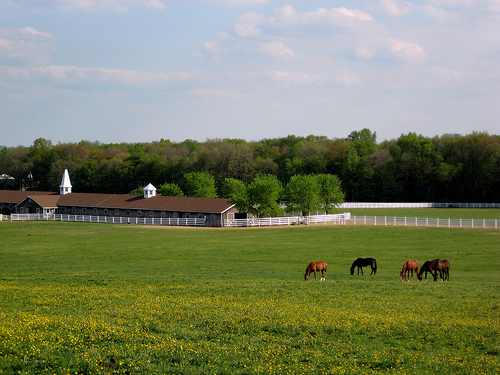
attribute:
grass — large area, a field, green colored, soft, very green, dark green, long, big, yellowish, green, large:
[4, 220, 499, 374]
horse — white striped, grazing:
[303, 261, 328, 280]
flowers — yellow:
[4, 298, 121, 363]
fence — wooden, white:
[8, 210, 490, 235]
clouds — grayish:
[247, 10, 410, 61]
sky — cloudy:
[0, 3, 499, 139]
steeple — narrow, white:
[59, 165, 73, 194]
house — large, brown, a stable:
[3, 169, 260, 230]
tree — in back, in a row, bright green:
[317, 174, 345, 218]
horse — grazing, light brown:
[399, 257, 420, 284]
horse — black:
[351, 259, 378, 275]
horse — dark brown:
[415, 257, 440, 283]